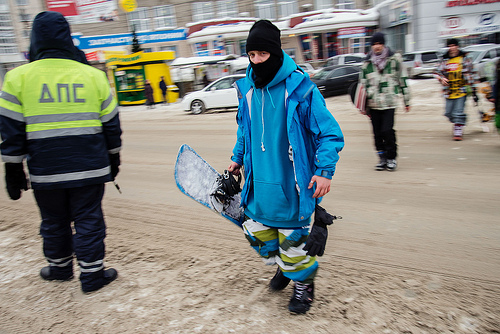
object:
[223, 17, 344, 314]
person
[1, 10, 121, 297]
man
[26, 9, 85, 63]
hat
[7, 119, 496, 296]
road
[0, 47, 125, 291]
clothes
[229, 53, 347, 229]
winter clothes